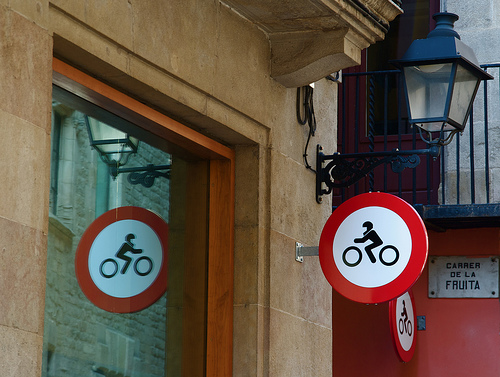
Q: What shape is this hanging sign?
A: Circle.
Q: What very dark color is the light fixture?
A: Black.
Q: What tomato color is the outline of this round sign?
A: Red.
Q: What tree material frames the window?
A: Wood.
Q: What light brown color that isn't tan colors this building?
A: Beige.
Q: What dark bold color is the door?
A: Red.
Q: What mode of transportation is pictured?
A: Bicycle.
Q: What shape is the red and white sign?
A: Circle.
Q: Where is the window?
A: Building.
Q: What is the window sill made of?
A: Wood.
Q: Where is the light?
A: Side of the building.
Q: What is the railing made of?
A: Wrought iron.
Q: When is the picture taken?
A: Daytime.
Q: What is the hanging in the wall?
A: Lamp.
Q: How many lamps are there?
A: One.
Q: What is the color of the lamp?
A: Black.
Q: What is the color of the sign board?
A: Red,black,and white.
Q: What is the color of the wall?
A: Brown.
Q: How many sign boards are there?
A: 2.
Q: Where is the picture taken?
A: Outside a city building.